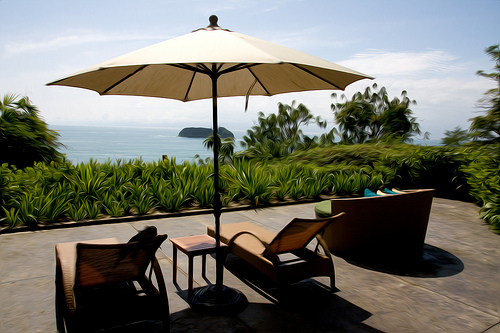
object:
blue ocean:
[68, 127, 152, 153]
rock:
[173, 123, 245, 143]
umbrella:
[45, 12, 377, 102]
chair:
[313, 184, 435, 252]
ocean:
[46, 124, 317, 165]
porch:
[0, 202, 498, 328]